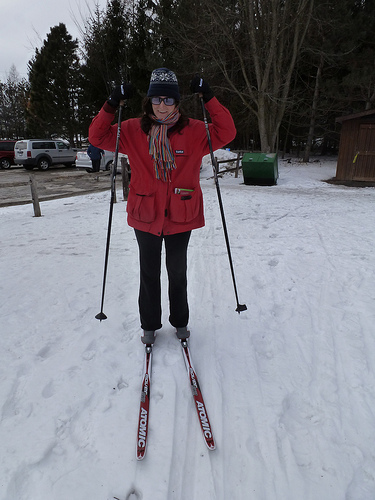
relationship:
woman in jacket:
[90, 67, 236, 341] [80, 84, 238, 230]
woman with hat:
[88, 67, 235, 346] [148, 66, 180, 97]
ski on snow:
[92, 89, 123, 318] [3, 180, 372, 499]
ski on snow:
[198, 79, 247, 311] [3, 180, 372, 499]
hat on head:
[143, 67, 188, 95] [136, 64, 192, 127]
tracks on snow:
[163, 350, 190, 500] [213, 202, 322, 448]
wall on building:
[332, 129, 373, 188] [324, 94, 367, 142]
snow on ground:
[0, 148, 373, 498] [2, 158, 372, 498]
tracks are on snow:
[189, 237, 238, 395] [243, 348, 345, 455]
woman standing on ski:
[90, 67, 236, 341] [175, 335, 218, 450]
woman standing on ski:
[90, 67, 236, 341] [135, 340, 156, 457]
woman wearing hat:
[90, 67, 236, 341] [137, 66, 183, 105]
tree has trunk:
[193, 0, 311, 161] [217, 0, 307, 152]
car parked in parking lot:
[9, 137, 82, 169] [1, 165, 126, 212]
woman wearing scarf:
[90, 67, 236, 341] [147, 113, 183, 174]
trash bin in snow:
[241, 150, 280, 184] [0, 148, 373, 498]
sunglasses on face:
[147, 89, 176, 109] [136, 62, 194, 125]